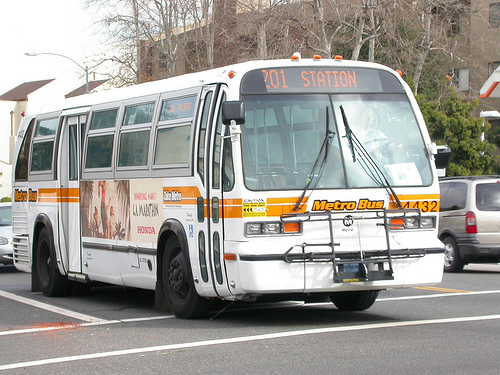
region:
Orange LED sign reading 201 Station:
[256, 60, 363, 97]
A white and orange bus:
[10, 53, 449, 329]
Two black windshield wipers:
[289, 100, 405, 216]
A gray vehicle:
[422, 166, 499, 273]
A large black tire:
[149, 222, 220, 323]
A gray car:
[0, 200, 25, 275]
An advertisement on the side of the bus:
[73, 172, 170, 253]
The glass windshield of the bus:
[235, 88, 435, 192]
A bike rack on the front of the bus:
[275, 203, 430, 285]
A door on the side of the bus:
[185, 78, 235, 305]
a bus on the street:
[2, 47, 449, 316]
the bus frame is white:
[0, 53, 445, 305]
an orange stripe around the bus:
[4, 182, 443, 218]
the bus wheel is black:
[155, 223, 202, 319]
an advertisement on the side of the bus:
[72, 178, 163, 248]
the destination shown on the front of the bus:
[260, 67, 382, 89]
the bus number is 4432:
[398, 199, 438, 216]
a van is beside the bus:
[435, 172, 498, 272]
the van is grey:
[434, 172, 499, 265]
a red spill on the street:
[14, 315, 88, 342]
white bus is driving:
[10, 51, 445, 319]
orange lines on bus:
[37, 186, 439, 218]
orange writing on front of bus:
[312, 199, 383, 211]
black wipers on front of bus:
[290, 104, 402, 213]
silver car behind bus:
[0, 200, 12, 267]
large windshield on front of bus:
[240, 93, 432, 189]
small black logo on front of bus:
[343, 215, 355, 227]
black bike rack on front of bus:
[280, 208, 422, 283]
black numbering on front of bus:
[402, 200, 437, 213]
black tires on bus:
[34, 226, 379, 321]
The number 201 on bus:
[252, 63, 293, 97]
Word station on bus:
[297, 63, 368, 100]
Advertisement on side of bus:
[75, 177, 186, 257]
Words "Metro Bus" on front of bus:
[309, 195, 392, 220]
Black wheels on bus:
[19, 222, 237, 322]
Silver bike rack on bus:
[271, 199, 441, 295]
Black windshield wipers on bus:
[261, 104, 426, 221]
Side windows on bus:
[22, 82, 218, 187]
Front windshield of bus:
[223, 87, 458, 195]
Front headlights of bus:
[228, 197, 448, 251]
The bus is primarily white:
[0, 60, 465, 332]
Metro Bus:
[313, 188, 385, 225]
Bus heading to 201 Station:
[256, 63, 381, 95]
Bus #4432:
[400, 200, 445, 218]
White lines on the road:
[23, 292, 476, 369]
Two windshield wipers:
[280, 85, 420, 210]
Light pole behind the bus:
[16, 45, 95, 100]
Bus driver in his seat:
[315, 104, 424, 190]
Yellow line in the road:
[413, 278, 470, 299]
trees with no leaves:
[63, 1, 471, 98]